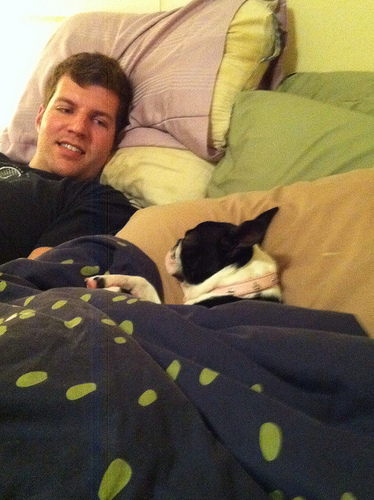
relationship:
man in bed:
[4, 51, 136, 244] [3, 292, 369, 497]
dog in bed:
[134, 202, 291, 307] [3, 292, 369, 497]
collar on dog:
[186, 277, 282, 297] [134, 202, 291, 307]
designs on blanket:
[17, 303, 142, 418] [13, 308, 361, 479]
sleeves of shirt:
[49, 187, 128, 242] [1, 163, 127, 245]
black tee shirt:
[19, 189, 65, 211] [1, 163, 127, 245]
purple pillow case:
[142, 8, 204, 113] [84, 10, 268, 126]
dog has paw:
[134, 202, 291, 307] [85, 261, 166, 310]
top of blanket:
[77, 256, 161, 318] [13, 308, 361, 479]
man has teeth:
[4, 51, 136, 244] [58, 141, 84, 159]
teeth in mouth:
[58, 141, 84, 159] [54, 134, 92, 164]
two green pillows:
[288, 51, 361, 152] [232, 69, 372, 182]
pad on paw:
[86, 278, 96, 288] [85, 261, 166, 310]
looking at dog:
[45, 98, 121, 128] [134, 202, 291, 307]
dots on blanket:
[8, 295, 115, 397] [13, 308, 361, 479]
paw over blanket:
[85, 261, 166, 310] [13, 308, 361, 479]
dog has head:
[134, 202, 291, 307] [163, 219, 275, 292]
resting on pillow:
[124, 207, 299, 343] [145, 187, 366, 316]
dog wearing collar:
[134, 202, 291, 307] [186, 277, 282, 297]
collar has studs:
[186, 277, 282, 297] [250, 278, 278, 290]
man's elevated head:
[4, 51, 136, 244] [32, 47, 142, 172]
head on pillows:
[32, 47, 142, 172] [60, 10, 239, 198]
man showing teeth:
[4, 51, 136, 244] [58, 141, 84, 159]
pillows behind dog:
[232, 69, 372, 182] [134, 202, 291, 307]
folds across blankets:
[66, 291, 279, 405] [13, 308, 361, 479]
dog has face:
[134, 202, 291, 307] [169, 219, 211, 280]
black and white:
[190, 235, 221, 263] [166, 250, 183, 276]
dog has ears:
[134, 202, 291, 307] [224, 193, 285, 256]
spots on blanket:
[17, 303, 142, 418] [13, 308, 361, 479]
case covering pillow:
[84, 10, 268, 126] [105, 11, 282, 175]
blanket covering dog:
[13, 308, 361, 479] [134, 202, 291, 307]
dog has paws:
[134, 202, 291, 307] [84, 258, 187, 324]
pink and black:
[85, 276, 99, 288] [95, 276, 106, 291]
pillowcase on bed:
[232, 69, 372, 182] [3, 292, 369, 497]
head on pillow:
[163, 219, 275, 292] [145, 187, 366, 316]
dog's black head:
[134, 202, 291, 307] [163, 219, 275, 292]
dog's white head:
[134, 202, 291, 307] [163, 219, 275, 292]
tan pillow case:
[314, 204, 347, 263] [273, 180, 368, 310]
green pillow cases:
[269, 111, 344, 166] [232, 69, 372, 182]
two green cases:
[288, 51, 361, 152] [232, 69, 372, 182]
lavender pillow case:
[142, 8, 204, 113] [84, 10, 268, 126]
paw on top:
[85, 261, 166, 310] [77, 256, 161, 318]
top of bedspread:
[77, 256, 161, 318] [13, 308, 361, 479]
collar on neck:
[186, 277, 282, 297] [179, 268, 298, 305]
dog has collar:
[134, 202, 291, 307] [186, 277, 282, 297]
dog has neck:
[134, 202, 291, 307] [179, 268, 298, 305]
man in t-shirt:
[4, 51, 136, 244] [1, 163, 127, 245]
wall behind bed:
[280, 0, 373, 79] [3, 292, 369, 497]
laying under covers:
[124, 207, 299, 343] [3, 292, 369, 497]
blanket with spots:
[13, 308, 361, 479] [17, 303, 142, 418]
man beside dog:
[4, 51, 136, 244] [134, 202, 291, 307]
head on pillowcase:
[163, 219, 275, 292] [273, 180, 368, 310]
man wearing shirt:
[4, 51, 136, 244] [1, 163, 127, 245]